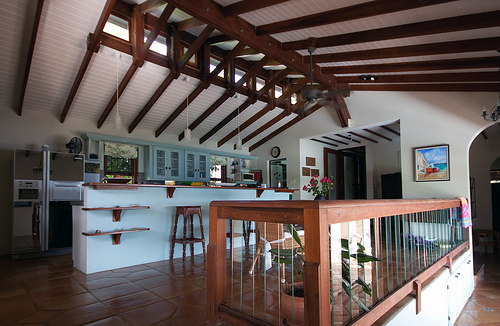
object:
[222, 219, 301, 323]
railing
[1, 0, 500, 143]
ceiling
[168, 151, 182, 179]
cupboard doors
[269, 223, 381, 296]
plant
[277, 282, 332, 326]
pot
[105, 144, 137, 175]
windows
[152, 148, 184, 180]
cabinets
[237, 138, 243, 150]
lights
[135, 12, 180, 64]
frames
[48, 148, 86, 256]
freezer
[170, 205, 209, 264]
stool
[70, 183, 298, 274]
bar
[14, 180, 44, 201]
ice maker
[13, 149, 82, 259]
refrigerator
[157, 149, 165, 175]
glass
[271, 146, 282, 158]
clock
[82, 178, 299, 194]
bar top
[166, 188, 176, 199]
wedge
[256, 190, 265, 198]
wedge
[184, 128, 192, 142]
light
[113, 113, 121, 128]
light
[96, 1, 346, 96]
wood trusses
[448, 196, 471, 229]
towel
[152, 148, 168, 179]
cupboard doors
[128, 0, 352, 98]
beams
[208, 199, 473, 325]
divider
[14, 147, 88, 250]
bar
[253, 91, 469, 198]
wall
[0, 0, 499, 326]
kitchen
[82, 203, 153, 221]
shelves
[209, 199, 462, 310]
bars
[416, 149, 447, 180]
painting